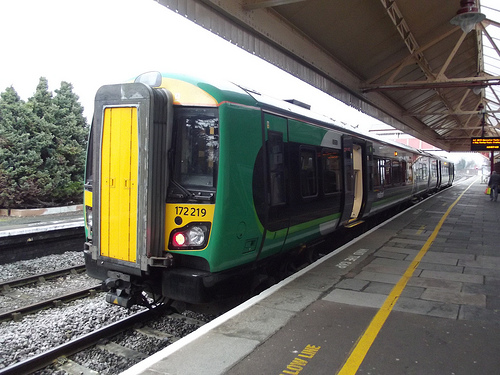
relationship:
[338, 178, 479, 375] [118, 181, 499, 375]
line on platform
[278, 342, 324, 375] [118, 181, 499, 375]
words on platform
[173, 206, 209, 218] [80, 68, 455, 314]
words on train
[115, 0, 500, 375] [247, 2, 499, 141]
station has beams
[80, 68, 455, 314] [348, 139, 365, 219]
train has door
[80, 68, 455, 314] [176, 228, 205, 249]
train has light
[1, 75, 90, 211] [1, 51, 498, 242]
trees in background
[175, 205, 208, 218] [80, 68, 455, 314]
numbers are on train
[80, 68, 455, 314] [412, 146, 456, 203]
train has cars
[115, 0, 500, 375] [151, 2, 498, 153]
station has overhang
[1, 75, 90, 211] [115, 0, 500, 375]
trees by station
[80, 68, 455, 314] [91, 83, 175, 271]
train has door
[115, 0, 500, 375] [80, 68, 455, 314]
station has train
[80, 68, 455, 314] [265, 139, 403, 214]
train has windows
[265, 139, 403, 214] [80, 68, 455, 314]
windows on side of train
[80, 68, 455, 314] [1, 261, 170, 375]
train has tracks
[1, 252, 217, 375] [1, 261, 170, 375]
gravel on tracks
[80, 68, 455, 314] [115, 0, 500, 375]
train stopped at station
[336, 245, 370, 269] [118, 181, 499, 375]
writing on platform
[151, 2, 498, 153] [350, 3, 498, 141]
overhang has frame